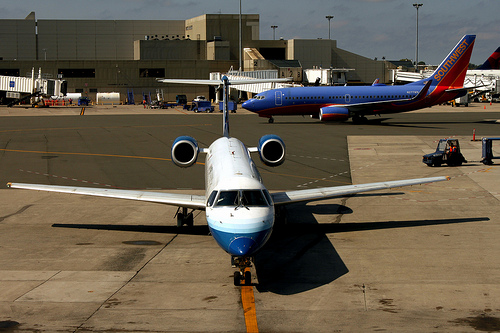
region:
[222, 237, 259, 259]
Front end of white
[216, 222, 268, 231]
Blue stripe on plane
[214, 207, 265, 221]
White paint on front of plane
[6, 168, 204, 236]
Left wing of plane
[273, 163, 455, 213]
Right wing of plane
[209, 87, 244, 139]
Body of tail of plane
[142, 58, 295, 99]
Top end of tail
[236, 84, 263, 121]
Front end of blue plane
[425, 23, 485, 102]
Tail end of blue plane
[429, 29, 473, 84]
Red lettering on plane tail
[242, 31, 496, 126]
Southwest blue and red airplane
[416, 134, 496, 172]
small vehicle for pulling baggage carts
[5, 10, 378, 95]
airport terminal building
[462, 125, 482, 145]
portable traffic control marker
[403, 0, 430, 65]
outdoor lighting fixture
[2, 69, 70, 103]
accordian style pullout gate to airplane connector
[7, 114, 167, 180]
part of airplane tarmac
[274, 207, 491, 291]
shadow of aircraft on tarmac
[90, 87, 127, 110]
white cylinder, barrel type container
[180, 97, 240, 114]
airplane baggage transporter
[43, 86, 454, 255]
airplane parked on tarmac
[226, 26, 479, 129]
Southwest airplane parked on tarmac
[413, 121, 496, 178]
man driving vehicle pulling luggage carts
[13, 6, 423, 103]
large airport terminal building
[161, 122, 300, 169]
two large engines on airplane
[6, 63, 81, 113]
ramp to load and unload passengers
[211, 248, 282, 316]
landing gear parked on yellow line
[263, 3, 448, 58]
large lamps around airport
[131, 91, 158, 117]
airport worker wearing orange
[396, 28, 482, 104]
Southwest logo on airplane tail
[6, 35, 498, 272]
two airplanes on tarmac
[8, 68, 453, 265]
airplane facing the camera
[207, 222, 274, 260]
airplane has blue nose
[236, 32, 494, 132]
airplane is blue and red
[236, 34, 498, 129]
airline is southwest airlines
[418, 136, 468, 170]
worker in vehicle on tarmac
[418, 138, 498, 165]
worker is driving toward plane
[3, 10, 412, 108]
airport terminal in background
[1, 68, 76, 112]
airport jetway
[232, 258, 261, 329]
plane on orange stripe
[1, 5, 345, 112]
Airport building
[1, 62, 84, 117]
Passenger ramp for airplanes on the left side of the photo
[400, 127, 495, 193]
Cargo moving vehicle on the right side of the photo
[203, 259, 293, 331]
Orange stripe in the center of the photo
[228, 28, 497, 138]
Blue commercial aircraft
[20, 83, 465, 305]
White commercial aircraft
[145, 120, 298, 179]
Front view of engines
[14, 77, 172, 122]
Workman in the background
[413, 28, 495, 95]
Southwest logo on tail fin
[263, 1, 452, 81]
Lights in the right background